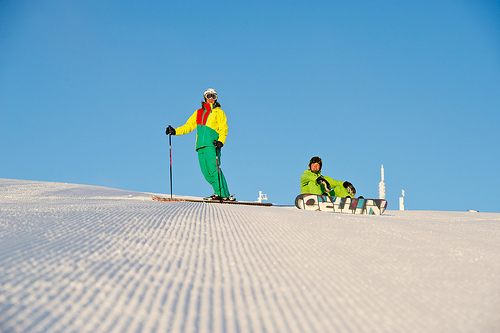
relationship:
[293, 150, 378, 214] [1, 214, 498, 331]
man on snow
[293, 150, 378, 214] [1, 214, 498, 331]
man sits snow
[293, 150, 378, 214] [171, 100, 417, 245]
man wears clothes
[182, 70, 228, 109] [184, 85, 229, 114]
person wears helmet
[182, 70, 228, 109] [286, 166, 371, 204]
person wears jacket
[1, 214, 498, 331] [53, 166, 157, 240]
snow on ground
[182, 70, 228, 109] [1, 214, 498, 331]
person on snow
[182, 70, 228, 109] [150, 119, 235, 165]
person wears gloves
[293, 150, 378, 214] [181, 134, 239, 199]
man wears pants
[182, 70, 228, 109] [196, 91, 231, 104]
person wears goggles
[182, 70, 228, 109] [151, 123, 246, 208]
person holds ski poles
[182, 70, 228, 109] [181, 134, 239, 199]
person wears pants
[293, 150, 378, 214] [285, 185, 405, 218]
man has snowboard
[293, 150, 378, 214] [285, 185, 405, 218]
man with snowboard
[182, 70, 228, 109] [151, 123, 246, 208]
person with ski poles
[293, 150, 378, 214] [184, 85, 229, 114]
man has helmet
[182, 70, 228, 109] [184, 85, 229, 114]
person has helmet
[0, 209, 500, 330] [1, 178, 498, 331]
ground has snow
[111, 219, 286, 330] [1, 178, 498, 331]
tracks on snow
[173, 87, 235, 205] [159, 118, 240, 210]
person holding skis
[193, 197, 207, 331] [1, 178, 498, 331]
groove in snow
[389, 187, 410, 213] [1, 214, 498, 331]
creation made snow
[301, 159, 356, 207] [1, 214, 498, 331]
man sitting snow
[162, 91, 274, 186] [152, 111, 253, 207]
woman on skis